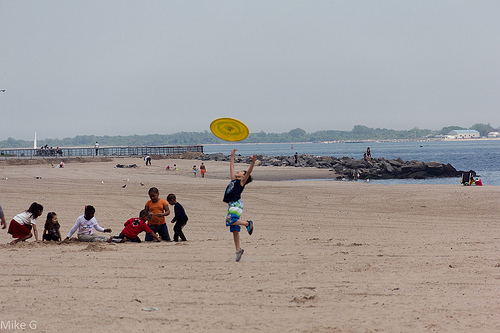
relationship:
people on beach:
[1, 184, 187, 243] [1, 153, 499, 330]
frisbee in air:
[210, 118, 251, 142] [3, 3, 500, 204]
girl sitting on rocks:
[365, 147, 373, 167] [331, 158, 482, 179]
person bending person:
[11, 204, 44, 245] [7, 200, 45, 245]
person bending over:
[165, 194, 190, 242] [164, 194, 188, 241]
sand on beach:
[1, 153, 499, 330] [7, 157, 484, 317]